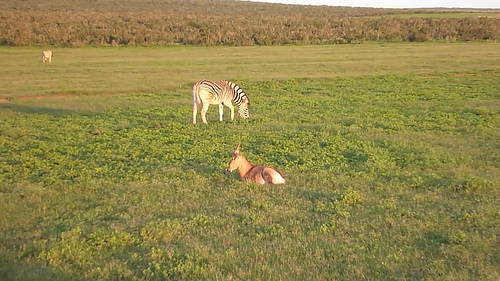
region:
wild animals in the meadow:
[30, 31, 350, 221]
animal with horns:
[218, 135, 284, 190]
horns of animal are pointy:
[231, 137, 242, 157]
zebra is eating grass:
[185, 74, 260, 126]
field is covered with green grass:
[5, 45, 498, 278]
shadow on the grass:
[0, 92, 179, 129]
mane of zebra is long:
[223, 79, 245, 100]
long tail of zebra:
[190, 79, 201, 109]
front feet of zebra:
[213, 97, 233, 122]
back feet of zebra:
[191, 103, 211, 128]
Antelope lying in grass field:
[227, 138, 283, 192]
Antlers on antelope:
[235, 135, 248, 150]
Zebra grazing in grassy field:
[185, 76, 257, 128]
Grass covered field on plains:
[10, 43, 496, 279]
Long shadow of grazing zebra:
[1, 96, 173, 126]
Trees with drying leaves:
[4, 2, 486, 48]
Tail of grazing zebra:
[191, 81, 205, 114]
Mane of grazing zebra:
[226, 80, 247, 102]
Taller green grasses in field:
[52, 214, 230, 275]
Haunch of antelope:
[259, 163, 289, 186]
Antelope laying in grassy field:
[225, 137, 287, 188]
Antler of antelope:
[235, 138, 244, 156]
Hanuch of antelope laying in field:
[258, 163, 286, 189]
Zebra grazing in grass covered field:
[186, 78, 253, 127]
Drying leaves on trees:
[1, 3, 497, 48]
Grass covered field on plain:
[1, 46, 494, 279]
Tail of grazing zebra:
[196, 82, 203, 107]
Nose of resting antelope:
[225, 165, 237, 174]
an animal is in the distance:
[38, 43, 53, 66]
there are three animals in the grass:
[39, 48, 286, 187]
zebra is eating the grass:
[189, 70, 254, 126]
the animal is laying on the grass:
[220, 136, 287, 186]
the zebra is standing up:
[186, 75, 252, 127]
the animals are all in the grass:
[36, 43, 297, 192]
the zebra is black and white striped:
[187, 76, 254, 126]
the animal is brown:
[218, 140, 289, 186]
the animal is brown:
[38, 47, 55, 64]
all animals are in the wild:
[40, 47, 289, 186]